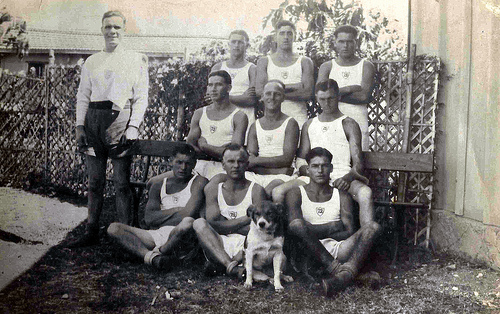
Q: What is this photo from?
A: An old yearbook.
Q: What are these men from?
A: A sports team.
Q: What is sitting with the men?
A: A dog.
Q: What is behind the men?
A: Metal fence.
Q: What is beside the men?
A: Old gray wall.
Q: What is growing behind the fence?
A: Trees.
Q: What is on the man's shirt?
A: A towel.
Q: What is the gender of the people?
A: Male.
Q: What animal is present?
A: Dog.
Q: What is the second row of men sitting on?
A: Bench.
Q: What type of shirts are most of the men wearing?
A: Tank top.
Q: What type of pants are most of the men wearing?
A: Shorts.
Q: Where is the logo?
A: Shirts.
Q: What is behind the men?
A: Fence.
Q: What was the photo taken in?
A: Black and white.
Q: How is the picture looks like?
A: Black and white.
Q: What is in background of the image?
A: Fence.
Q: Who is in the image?
A: A coach with players.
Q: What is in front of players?
A: Dog.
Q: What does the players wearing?
A: White top tanks.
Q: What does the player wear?
A: White shorts.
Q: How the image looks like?
A: Black and white.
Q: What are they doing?
A: Sitting outside.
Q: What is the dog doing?
A: Sitting in front of the men.